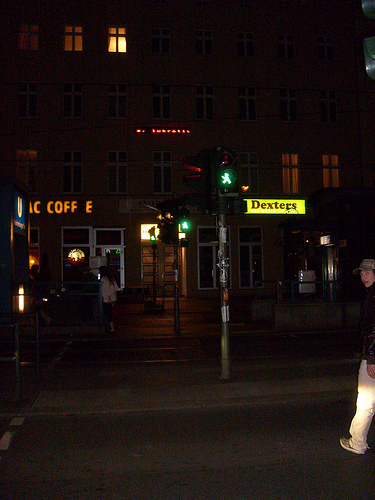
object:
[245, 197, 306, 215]
sign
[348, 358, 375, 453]
pants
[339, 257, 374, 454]
man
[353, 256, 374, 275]
hat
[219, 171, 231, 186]
light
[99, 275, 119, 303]
jacket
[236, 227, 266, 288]
window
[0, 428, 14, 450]
line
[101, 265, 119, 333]
woman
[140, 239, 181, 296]
doorway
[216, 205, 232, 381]
pole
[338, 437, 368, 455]
shoe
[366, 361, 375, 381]
hand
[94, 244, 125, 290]
window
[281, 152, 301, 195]
curtain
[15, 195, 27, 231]
sign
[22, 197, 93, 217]
sign